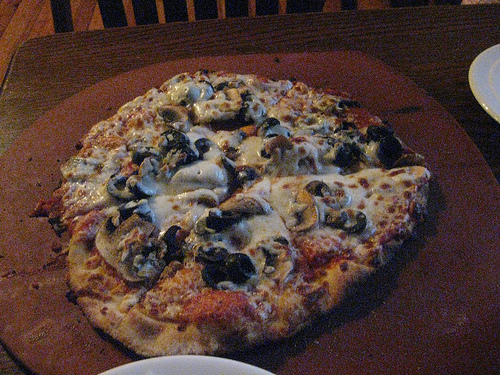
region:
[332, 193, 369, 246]
a black olive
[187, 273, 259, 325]
red pizza sauce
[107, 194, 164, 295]
a large brown mushroom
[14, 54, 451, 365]
pizza on a pizza plate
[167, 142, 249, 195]
melted cheese on a pizza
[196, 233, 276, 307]
pile of olives in a pizza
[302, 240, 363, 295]
cooked pizza crust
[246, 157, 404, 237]
melted browned mozzarella cheese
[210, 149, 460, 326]
a slice of pizza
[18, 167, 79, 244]
pizza sauce on the crust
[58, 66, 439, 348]
a pizza on a stone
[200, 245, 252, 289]
olives on a pizza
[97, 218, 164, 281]
mushroom on a pizza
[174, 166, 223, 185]
cheese on a pizza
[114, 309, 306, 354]
crust of a pizza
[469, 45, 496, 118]
edge of a white ceramic plate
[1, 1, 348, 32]
wooden rods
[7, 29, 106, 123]
the corner of a wooden table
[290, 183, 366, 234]
mushrooms and cheese on a pizza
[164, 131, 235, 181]
olives and cheese on a pizza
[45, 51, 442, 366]
pizza with olives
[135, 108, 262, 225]
cheese on a pizza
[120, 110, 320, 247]
chese and olives on a pizza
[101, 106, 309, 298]
olives and cheese on a pizza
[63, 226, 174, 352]
crust of a pizza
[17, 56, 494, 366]
pizza on a table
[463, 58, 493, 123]
part of a white plate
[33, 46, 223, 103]
brown table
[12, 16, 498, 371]
brown round table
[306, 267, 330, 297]
part of a pizza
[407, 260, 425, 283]
part of a shade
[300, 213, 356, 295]
part of a pizza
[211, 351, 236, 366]
edge of a pizza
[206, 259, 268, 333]
part of a pizza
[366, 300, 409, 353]
part of a pizza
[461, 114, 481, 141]
part of a table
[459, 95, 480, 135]
part of a table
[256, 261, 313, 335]
part of a pizza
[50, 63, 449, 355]
cheese and meat pizza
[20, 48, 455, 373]
pizza on a broad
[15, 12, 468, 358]
pizza sitting on a table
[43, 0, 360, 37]
a chair against the table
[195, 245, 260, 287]
black olives on a pizza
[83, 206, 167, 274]
murshrooms on a pizza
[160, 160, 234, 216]
cheese on a pizza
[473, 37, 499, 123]
white and yellow plate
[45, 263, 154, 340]
A thin crust pizza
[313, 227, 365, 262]
pizza sauce on a pizza